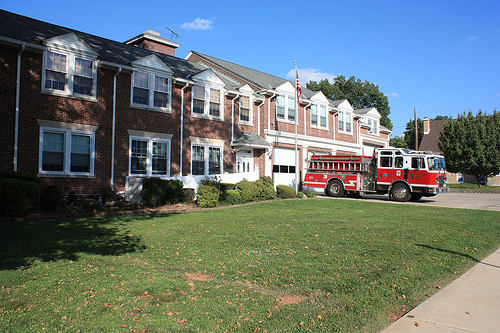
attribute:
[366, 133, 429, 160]
floor — first, lower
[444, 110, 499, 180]
leaves — are verdant, are vibrant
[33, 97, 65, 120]
brick — small, tight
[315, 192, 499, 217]
driveway — gray, cement, flat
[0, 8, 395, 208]
fire department — large, brick, chimneyed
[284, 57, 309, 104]
flag — American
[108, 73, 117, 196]
drain — long, narrow, metal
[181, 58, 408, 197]
firehouse — large, brick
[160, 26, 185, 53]
antenna — television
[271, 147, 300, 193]
door — large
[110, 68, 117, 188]
downpipe — long, narrow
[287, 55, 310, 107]
american flag — red, white, blue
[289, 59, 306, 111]
plant — window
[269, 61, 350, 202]
pole — long, tall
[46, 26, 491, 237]
building — red, brick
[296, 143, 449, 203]
fire truck — polished, vacant, gray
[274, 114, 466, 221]
fire truck — red, white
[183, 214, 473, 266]
grass — short, dry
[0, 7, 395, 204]
house — brick, two-story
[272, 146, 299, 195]
door — closed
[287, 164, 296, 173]
window — small, glass, clear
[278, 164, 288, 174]
window — glass, small, clear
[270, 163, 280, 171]
window — small, glass, clear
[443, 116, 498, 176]
tree — green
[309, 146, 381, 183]
ladder — shiny, long, extendable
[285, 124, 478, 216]
firetruck — black, red, white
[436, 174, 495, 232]
driveway — flat, gray, cement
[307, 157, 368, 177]
ladder — silver, expanding, tall, sturdy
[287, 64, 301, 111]
flag — draping, swirling, American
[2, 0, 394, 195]
fire house — huge, brick, official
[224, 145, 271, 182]
doors — are white, are windowed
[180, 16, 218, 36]
cloud — beautiful, airy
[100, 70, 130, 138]
wall — brick, shady, two-story, multi-color, obscured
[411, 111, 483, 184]
trees — are tall, are distant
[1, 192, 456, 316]
front lawn — large, trimmed, open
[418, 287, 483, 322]
sidewalk — gray, cement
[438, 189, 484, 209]
sidewalk — gray, cement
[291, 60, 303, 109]
flag — American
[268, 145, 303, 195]
garage — locked, white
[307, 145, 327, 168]
garage — locked, white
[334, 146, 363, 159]
garage — locked, white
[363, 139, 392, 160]
garage — locked, white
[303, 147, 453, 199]
firetruck — large, red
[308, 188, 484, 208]
drive — cement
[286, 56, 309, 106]
flag — American, red, white, blue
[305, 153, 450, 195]
fire truck — red, white, parked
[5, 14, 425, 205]
building — large, tidy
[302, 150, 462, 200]
fire truck — shiny, red, white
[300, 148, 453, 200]
fire truck — red, black, white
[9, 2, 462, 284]
fire department — operating, large, government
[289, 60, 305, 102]
flag — American, red, white, blue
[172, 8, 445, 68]
sky — azure, brilliant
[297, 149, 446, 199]
truck — fire, red, white, black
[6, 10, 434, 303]
fire department — sizable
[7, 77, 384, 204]
building — long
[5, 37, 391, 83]
roof — black, tar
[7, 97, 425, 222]
building — red, black, brick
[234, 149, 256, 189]
door — white